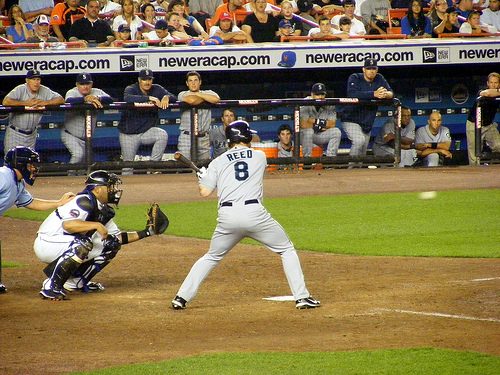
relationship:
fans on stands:
[3, 1, 498, 44] [4, 0, 498, 82]